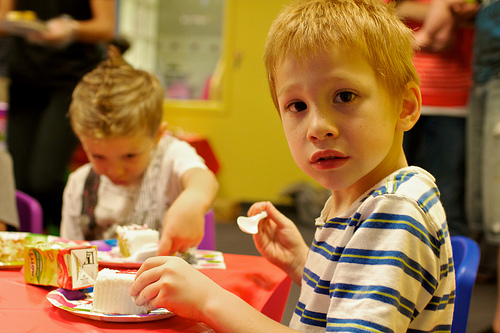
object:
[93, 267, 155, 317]
cake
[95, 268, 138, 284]
frosting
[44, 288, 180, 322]
plate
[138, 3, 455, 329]
boy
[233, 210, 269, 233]
spoon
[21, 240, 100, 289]
juice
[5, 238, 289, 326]
table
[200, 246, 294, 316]
tablecloth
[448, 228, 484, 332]
chair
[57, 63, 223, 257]
boy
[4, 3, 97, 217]
lady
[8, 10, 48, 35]
plate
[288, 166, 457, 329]
shirt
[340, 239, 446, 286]
stripes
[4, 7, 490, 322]
image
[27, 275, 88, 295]
side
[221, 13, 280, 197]
wall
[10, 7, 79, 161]
clothes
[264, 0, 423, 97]
hair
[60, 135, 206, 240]
shirt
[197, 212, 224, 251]
chair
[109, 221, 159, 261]
cake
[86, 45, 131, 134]
mohawk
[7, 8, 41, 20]
cake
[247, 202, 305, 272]
hand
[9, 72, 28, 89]
black